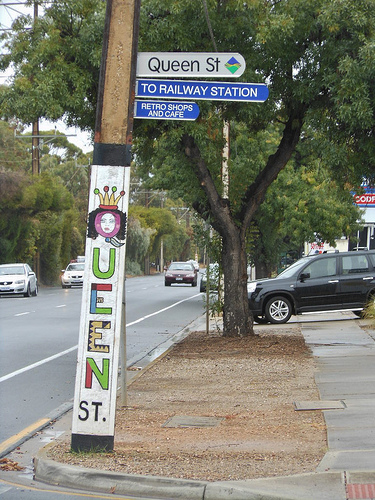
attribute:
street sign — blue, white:
[134, 77, 270, 104]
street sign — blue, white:
[132, 101, 201, 123]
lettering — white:
[140, 83, 259, 97]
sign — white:
[136, 52, 247, 77]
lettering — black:
[147, 56, 222, 73]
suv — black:
[248, 250, 374, 324]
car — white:
[60, 260, 83, 289]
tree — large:
[1, 2, 374, 338]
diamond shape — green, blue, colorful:
[223, 56, 242, 78]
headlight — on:
[58, 272, 74, 282]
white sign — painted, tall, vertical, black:
[70, 143, 138, 455]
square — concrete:
[293, 398, 346, 413]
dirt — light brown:
[154, 345, 308, 469]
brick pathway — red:
[345, 483, 374, 499]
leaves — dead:
[1, 446, 35, 482]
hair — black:
[86, 208, 128, 239]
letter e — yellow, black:
[87, 320, 112, 352]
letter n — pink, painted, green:
[84, 357, 111, 390]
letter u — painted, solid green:
[91, 247, 116, 280]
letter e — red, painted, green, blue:
[88, 282, 115, 316]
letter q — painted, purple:
[94, 210, 123, 249]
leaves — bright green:
[0, 2, 372, 192]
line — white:
[1, 293, 202, 392]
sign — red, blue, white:
[349, 184, 374, 212]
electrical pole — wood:
[31, 1, 41, 183]